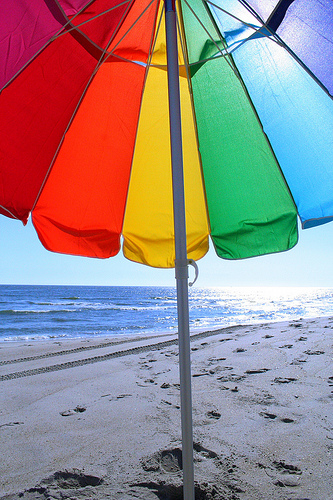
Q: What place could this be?
A: It is a beach.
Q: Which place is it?
A: It is a beach.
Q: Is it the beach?
A: Yes, it is the beach.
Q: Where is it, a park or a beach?
A: It is a beach.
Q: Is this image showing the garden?
A: No, the picture is showing the beach.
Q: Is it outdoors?
A: Yes, it is outdoors.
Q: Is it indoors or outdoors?
A: It is outdoors.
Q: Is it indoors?
A: No, it is outdoors.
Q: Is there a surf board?
A: No, there are no surfboards.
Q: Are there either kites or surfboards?
A: No, there are no surfboards or kites.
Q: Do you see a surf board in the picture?
A: No, there are no surfboards.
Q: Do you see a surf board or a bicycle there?
A: No, there are no surfboards or bicycles.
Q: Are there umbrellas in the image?
A: Yes, there is an umbrella.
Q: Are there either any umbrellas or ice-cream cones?
A: Yes, there is an umbrella.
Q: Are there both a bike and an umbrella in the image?
A: No, there is an umbrella but no bikes.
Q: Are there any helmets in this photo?
A: No, there are no helmets.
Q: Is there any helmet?
A: No, there are no helmets.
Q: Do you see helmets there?
A: No, there are no helmets.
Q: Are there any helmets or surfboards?
A: No, there are no helmets or surfboards.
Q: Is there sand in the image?
A: Yes, there is sand.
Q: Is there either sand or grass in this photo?
A: Yes, there is sand.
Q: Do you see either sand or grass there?
A: Yes, there is sand.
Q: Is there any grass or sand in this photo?
A: Yes, there is sand.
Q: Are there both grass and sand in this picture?
A: No, there is sand but no grass.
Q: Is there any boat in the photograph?
A: No, there are no boats.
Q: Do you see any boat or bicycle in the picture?
A: No, there are no boats or bicycles.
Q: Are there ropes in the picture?
A: No, there are no ropes.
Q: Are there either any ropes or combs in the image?
A: No, there are no ropes or combs.